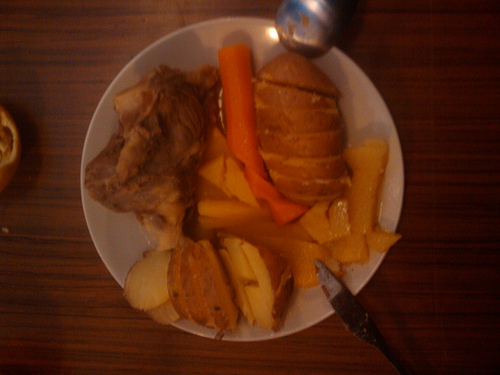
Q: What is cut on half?
A: Carrots.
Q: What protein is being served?
A: Meat.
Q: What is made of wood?
A: Table.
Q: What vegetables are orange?
A: Carrots.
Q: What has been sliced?
A: Potato.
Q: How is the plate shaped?
A: Round.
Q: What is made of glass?
A: Plate.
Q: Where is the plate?
A: Under the food.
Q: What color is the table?
A: Brown.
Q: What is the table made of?
A: Wood.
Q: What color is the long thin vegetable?
A: Orange.